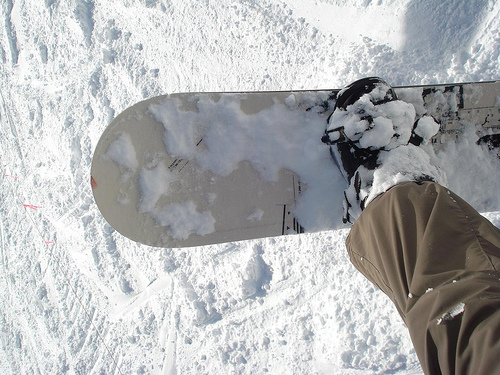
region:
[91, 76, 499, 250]
snow on the snowboard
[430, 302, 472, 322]
bit of snow on the pants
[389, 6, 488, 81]
shadow on the ground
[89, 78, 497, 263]
cream and black snow board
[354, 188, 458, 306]
wrinkles in the pants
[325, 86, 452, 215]
snow on the foot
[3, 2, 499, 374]
snow on the ground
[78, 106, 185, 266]
round tip of the board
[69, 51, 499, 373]
person standing on a snowboard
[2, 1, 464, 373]
snow is not smooth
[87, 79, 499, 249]
a white and black snowboard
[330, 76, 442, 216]
a black boot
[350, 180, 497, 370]
a khaki colored pant leg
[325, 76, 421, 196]
a black boot covered in snow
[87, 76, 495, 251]
a snowboard with clumps of snow on it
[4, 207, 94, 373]
tracks in the snow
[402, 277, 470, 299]
tiny bits of snow on a khaki pant leg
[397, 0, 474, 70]
a shadow in the snow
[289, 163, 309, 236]
black stripes on the snowboard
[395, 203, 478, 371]
wrinkles in a pant leg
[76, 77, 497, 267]
a white snowboard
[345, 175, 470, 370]
a leg from brown pants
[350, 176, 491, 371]
a brown pant leg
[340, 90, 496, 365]
a person's left leg on a snowboard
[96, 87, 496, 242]
a snowboard that is covered in snow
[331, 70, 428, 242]
a boot that is covered in snow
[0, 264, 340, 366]
fresh white snow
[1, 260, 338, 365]
the snow looks soft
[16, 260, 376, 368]
the snow is white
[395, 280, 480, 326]
small chunks of snow on someone's pants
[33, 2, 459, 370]
A lot of snow around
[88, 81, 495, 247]
A snowboard being used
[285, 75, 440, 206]
A black shoe on the snowboard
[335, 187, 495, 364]
Tan pants being worn by a person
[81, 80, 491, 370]
A person is going snowboarding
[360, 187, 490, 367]
A person's leg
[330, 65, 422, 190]
Snow is covering the shoe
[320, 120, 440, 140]
The snowboard has a strap to be placed on the shoe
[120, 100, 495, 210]
Snow is all over the snowboard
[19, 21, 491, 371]
The snow is beautifully white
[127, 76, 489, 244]
person doing trick on snowboard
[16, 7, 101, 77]
whie snow on hill side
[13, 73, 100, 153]
whie snow on hill side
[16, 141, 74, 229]
whie snow on hill side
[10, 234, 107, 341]
whie snow on hill side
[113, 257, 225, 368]
whie snow on hill side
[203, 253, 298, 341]
whie snow on hill side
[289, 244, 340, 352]
whie snow on hill side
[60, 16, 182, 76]
whie snow on hill side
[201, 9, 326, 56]
whie snow on hill side